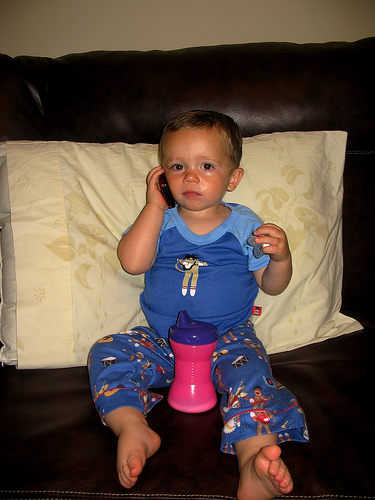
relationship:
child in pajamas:
[87, 108, 301, 499] [81, 198, 315, 447]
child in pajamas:
[69, 101, 336, 497] [81, 198, 315, 447]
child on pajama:
[87, 108, 301, 499] [87, 196, 309, 454]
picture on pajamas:
[170, 252, 212, 300] [81, 198, 315, 447]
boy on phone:
[85, 109, 309, 497] [150, 162, 176, 210]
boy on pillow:
[75, 94, 318, 485] [16, 137, 362, 364]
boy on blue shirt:
[117, 110, 292, 472] [166, 218, 250, 319]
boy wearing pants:
[102, 118, 342, 483] [113, 319, 291, 441]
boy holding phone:
[85, 109, 309, 497] [155, 170, 176, 210]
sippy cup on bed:
[158, 306, 224, 413] [10, 43, 372, 497]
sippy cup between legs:
[168, 309, 219, 413] [86, 320, 308, 495]